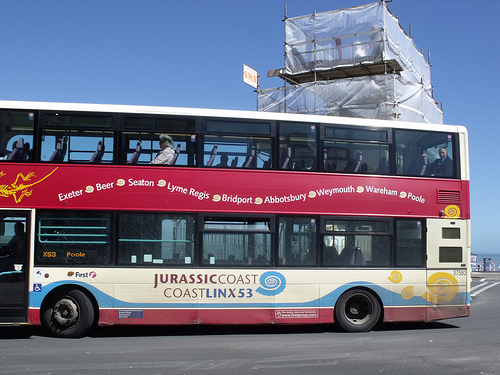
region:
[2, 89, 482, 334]
two level bus transporting passengers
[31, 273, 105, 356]
slightly turned wheel on a bus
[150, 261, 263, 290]
red words saying "Jurassic Coast"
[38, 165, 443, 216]
white words on the red portion of the bus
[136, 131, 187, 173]
woman sitting on the upper level of the bus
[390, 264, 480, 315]
yellow sign on the back of the bus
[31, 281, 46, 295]
blue handicap sign near bus door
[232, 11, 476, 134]
structure wrapped in plastic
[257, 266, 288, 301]
blue swirl design on the side of the bus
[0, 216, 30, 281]
driver sitting in his seat on the bus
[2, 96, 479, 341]
double decker bus on a clear day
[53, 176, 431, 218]
Names of towns in England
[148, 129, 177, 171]
person sitting in top level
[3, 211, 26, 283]
bus driver in front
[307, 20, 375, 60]
white fabric covering structure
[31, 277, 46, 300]
blue handicap sign on bus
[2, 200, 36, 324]
bus door on front first level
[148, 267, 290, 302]
words on side of bus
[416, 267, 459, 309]
yellow swirl on back of bus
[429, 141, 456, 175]
man sitting at rear on top level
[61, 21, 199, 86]
the sky is blue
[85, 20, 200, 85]
the sky is clear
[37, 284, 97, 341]
the tires are black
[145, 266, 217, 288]
the bus says jurassic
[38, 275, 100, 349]
the tire is round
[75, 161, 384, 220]
the sign is red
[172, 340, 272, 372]
the ground is gray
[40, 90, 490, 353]
the bus is two stories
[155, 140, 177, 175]
the shirt is white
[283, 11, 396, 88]
the tarp is white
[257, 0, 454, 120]
tall scaffolding with plastic sheeting walls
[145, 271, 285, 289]
purple lettering reading JURASSICCOAST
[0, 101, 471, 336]
double deck touring bus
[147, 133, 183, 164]
man in white seated in upper window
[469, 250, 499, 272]
small glimps of the ocean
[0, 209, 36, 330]
bus door with driver visible through it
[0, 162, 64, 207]
yellow animal skeleton painted on top deck of bus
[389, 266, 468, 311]
abstract yellow shells painted on bus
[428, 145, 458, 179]
man in black seated in very back of top deck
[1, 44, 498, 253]
cloud free blue sky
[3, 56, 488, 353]
Picture of a double decker bus.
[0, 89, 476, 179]
Top section double decker bus.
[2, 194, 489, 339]
Bottom section double decker bus.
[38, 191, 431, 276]
Passenger windows on botton section of bus.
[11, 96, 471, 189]
Passenger windows top section of bus.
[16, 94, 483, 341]
A pink and white bus.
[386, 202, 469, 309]
Yellow graphics on back of bus.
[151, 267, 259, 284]
The word JURASSICCOASTon side of bus.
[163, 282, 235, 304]
The words COASTLINX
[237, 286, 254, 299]
The number 53.